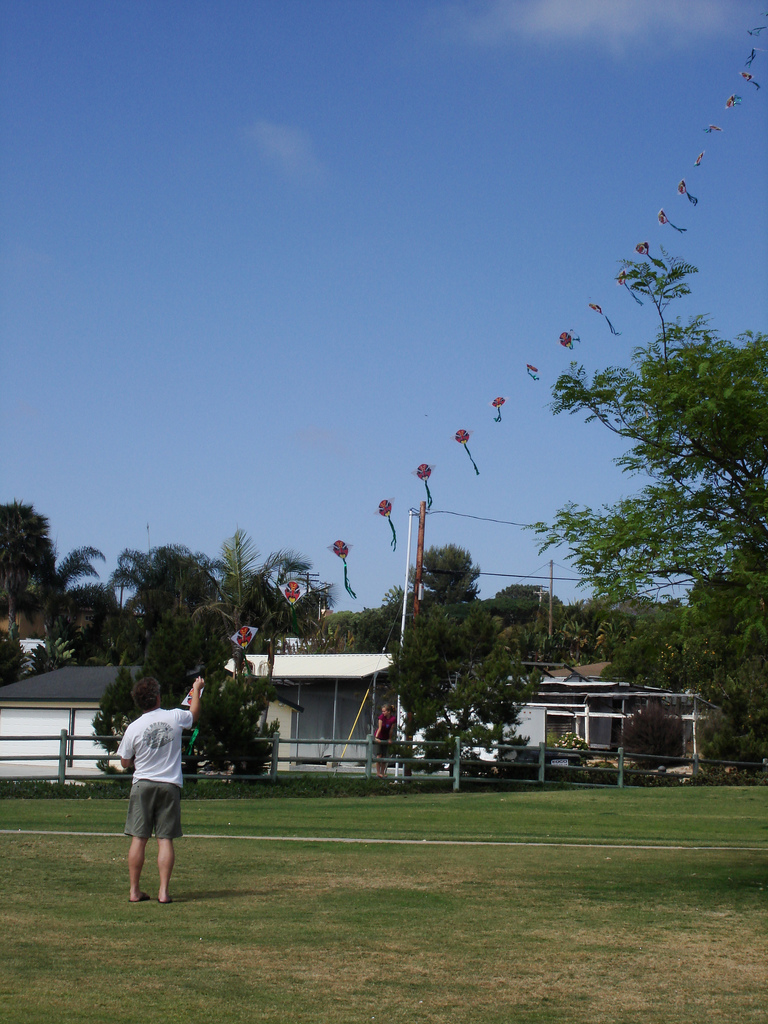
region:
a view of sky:
[158, 106, 343, 277]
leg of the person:
[151, 813, 273, 947]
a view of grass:
[274, 843, 453, 942]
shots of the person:
[81, 785, 281, 883]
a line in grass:
[403, 807, 556, 896]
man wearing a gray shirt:
[119, 698, 183, 790]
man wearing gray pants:
[110, 778, 186, 842]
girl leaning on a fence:
[350, 697, 403, 769]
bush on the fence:
[606, 680, 680, 783]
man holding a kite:
[180, 638, 220, 704]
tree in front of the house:
[207, 649, 282, 758]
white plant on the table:
[542, 719, 585, 753]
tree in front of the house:
[607, 690, 685, 778]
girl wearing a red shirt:
[370, 710, 396, 730]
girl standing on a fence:
[371, 700, 398, 775]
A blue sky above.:
[1, 4, 766, 597]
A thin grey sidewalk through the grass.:
[1, 829, 766, 853]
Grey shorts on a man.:
[122, 778, 183, 839]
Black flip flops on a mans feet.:
[129, 891, 172, 904]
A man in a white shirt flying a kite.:
[116, 676, 204, 904]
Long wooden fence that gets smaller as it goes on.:
[1, 730, 766, 790]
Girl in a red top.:
[373, 702, 397, 777]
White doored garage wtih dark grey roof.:
[0, 663, 306, 770]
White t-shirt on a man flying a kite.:
[116, 706, 194, 791]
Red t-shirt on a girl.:
[375, 710, 396, 741]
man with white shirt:
[73, 656, 239, 916]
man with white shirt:
[77, 666, 224, 915]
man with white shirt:
[76, 655, 232, 935]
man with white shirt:
[70, 634, 236, 922]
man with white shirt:
[75, 641, 220, 907]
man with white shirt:
[75, 651, 225, 916]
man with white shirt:
[70, 653, 226, 921]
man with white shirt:
[80, 665, 221, 919]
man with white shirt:
[82, 651, 215, 904]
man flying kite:
[81, 662, 223, 905]